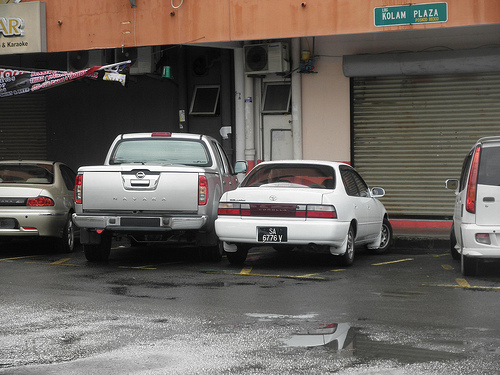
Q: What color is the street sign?
A: Green.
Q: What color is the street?
A: Black.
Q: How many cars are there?
A: Four.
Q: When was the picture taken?
A: Daytime.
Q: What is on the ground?
A: Water.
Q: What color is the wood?
A: Brown.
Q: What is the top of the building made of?
A: Wood.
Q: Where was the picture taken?
A: In a parking lot.